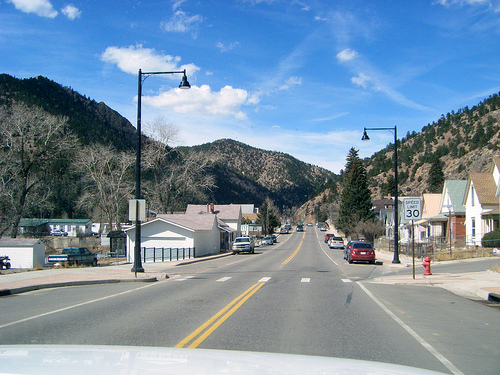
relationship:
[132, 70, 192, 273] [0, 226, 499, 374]
street light over road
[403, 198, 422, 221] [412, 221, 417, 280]
sign on top of pole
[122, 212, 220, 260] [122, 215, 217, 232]
house has roof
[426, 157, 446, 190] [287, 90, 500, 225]
tree on top of mountainside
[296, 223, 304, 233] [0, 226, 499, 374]
vehicle driving up road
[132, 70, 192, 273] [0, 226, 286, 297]
street light on top of sidewalk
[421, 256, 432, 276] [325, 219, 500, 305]
fire hydrant on top of sidewalk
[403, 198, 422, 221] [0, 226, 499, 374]
sign on top of road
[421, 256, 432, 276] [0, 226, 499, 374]
fire hydrant on top of road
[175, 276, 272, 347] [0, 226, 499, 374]
line on top of road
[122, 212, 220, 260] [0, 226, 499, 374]
house on side of road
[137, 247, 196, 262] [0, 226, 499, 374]
fence on side of road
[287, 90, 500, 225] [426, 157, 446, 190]
mountainside has tree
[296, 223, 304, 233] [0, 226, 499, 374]
vehicle driving on top of road